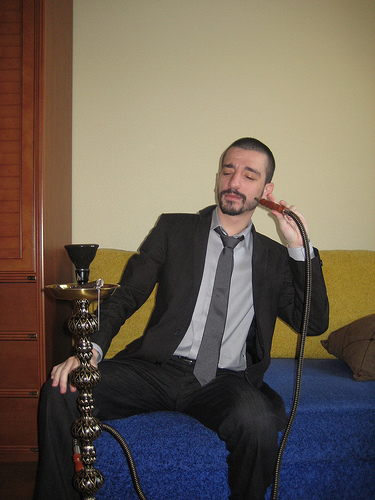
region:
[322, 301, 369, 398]
The brown pillow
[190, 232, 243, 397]
The mans gray tie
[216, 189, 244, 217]
The mans goatee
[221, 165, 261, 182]
The mans closed eyes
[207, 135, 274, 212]
The mans whole head, neck up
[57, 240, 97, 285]
Sheesha container, black on the top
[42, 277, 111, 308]
The hookah ash tray top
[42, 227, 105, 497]
The entire hookah body left side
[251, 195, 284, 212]
The hookah mouth peice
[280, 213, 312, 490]
The hookah tube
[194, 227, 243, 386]
grey tie slightly loosened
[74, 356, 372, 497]
bed covering with light and dark blue spots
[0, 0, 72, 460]
wooden dresser with three drawers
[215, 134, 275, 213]
man's face with eyes closed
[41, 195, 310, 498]
hookah with single nozzle and multiple chambers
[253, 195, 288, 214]
mahogany-colored wood nozzle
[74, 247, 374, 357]
large yellow pillow on side of bed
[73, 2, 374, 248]
unadorned beige wall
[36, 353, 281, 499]
lightweight suit pants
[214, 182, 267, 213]
well-trimmed beard and goatee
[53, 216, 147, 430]
a very big bong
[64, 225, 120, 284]
the top of a big bong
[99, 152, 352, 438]
a man sitting on a bed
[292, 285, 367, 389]
a pillow on a bed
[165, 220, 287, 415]
a man wearing a grey tie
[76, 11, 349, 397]
a man wearing a black suit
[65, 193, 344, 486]
a man sitting on a blue bed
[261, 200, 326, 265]
a man holding a tube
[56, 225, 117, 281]
a black bowl of a bong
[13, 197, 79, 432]
a wooden dressor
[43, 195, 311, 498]
Large black and gold hookah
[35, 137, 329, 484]
Man in a suit smoking a hookah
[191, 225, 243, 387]
Solid grey tie on a man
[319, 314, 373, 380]
Brown pillow on a bed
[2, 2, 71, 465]
Large wooden protruding closet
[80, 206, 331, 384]
Dark grey suit jacket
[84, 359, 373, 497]
Royal blue bed spread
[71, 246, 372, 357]
Large mustard yellow body pillow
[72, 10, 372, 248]
Off white painted wall of a room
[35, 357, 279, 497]
Grey suit pants worn by a man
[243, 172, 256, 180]
MAN EYES ARE CLOSED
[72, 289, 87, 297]
GOLD TRIMMING AT THE TOP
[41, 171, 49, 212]
CABINET IS MADE OF WOOD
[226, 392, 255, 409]
MAN IS WEARING DARK PANTS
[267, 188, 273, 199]
MAN FINGER IS ON THE EAR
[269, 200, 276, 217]
MAN IS HOLDING A HOOKAH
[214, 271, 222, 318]
MAN IS WEARING A GREY TIE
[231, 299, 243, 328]
MAN HAS ON A LIGHT GREY SHIRT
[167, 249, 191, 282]
MAN IS WEARING A SUIT JACKET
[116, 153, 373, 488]
MAN IS SITTING ON A SOFA